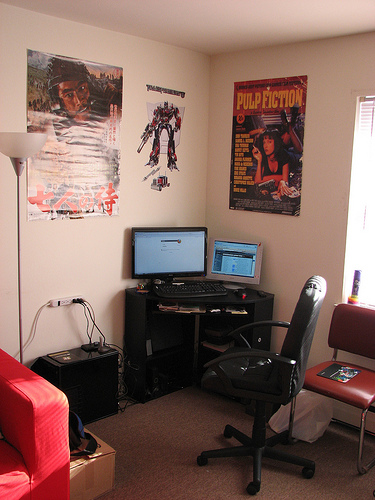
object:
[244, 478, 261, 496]
wheel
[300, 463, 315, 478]
wheel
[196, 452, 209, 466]
wheel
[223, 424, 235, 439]
wheel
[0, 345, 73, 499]
chair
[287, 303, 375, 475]
chair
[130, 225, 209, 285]
computer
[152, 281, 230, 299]
keyboard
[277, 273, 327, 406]
back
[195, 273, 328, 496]
chair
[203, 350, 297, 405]
arm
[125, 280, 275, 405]
black desk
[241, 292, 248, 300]
mouse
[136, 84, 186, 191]
poster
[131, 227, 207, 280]
monitor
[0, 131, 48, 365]
lamp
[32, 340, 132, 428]
computer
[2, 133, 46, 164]
shade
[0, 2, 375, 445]
wall